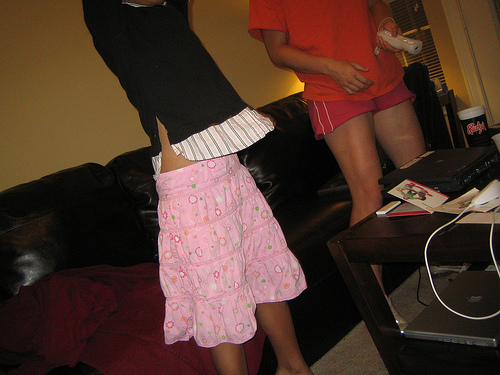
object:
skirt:
[153, 151, 308, 348]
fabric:
[2, 264, 213, 374]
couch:
[6, 92, 453, 373]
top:
[81, 1, 275, 152]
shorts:
[306, 79, 416, 141]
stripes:
[312, 101, 334, 134]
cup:
[456, 103, 490, 148]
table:
[326, 156, 499, 374]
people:
[82, 1, 425, 374]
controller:
[375, 29, 424, 56]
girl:
[83, 2, 310, 374]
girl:
[247, 3, 425, 331]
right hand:
[333, 57, 376, 97]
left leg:
[254, 302, 314, 374]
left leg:
[372, 100, 425, 169]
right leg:
[208, 343, 249, 374]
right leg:
[317, 112, 384, 293]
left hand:
[376, 23, 402, 54]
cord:
[423, 205, 499, 320]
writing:
[465, 120, 487, 137]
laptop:
[402, 271, 499, 347]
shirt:
[248, 2, 406, 102]